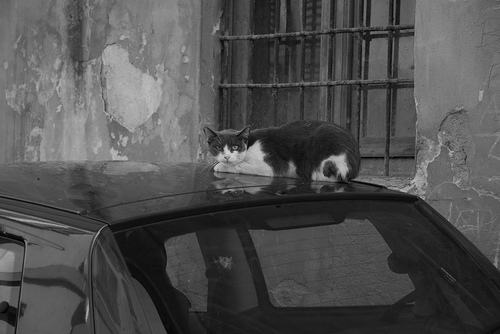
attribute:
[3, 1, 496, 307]
wall — concrete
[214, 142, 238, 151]
eyes — LIGHT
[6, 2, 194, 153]
wall — damaged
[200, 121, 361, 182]
cat — BLACK, WHITE, RECLINED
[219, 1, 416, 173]
bars — SOME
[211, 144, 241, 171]
nose — WHITE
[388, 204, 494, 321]
windshield wiper — CAR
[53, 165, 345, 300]
car — small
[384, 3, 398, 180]
pole — rusted, metal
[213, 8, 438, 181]
bar — METAL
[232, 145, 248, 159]
whiskers — WHITE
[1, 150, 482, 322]
car — BLACK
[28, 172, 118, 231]
paint — CAR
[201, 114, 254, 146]
ears — CAT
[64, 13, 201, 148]
wall — CONCRETE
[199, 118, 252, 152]
ears — POINTY